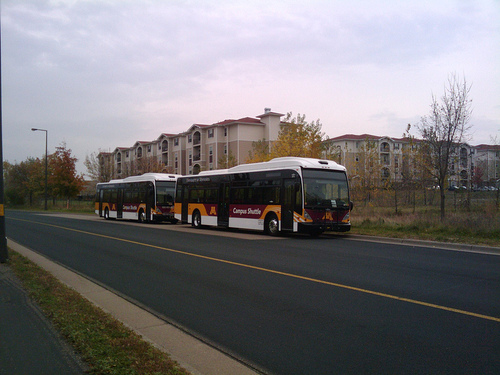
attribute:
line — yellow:
[17, 203, 499, 373]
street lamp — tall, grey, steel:
[32, 127, 48, 211]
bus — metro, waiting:
[176, 167, 364, 240]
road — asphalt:
[8, 206, 498, 370]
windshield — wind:
[297, 167, 356, 206]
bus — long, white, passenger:
[158, 149, 373, 233]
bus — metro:
[178, 147, 365, 258]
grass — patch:
[7, 245, 191, 373]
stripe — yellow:
[32, 215, 496, 363]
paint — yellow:
[187, 201, 222, 212]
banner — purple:
[209, 196, 300, 231]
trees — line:
[1, 145, 92, 218]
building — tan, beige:
[96, 108, 306, 180]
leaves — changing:
[53, 160, 72, 187]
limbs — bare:
[421, 78, 478, 173]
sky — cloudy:
[0, 0, 499, 182]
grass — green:
[0, 238, 198, 373]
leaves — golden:
[258, 114, 348, 157]